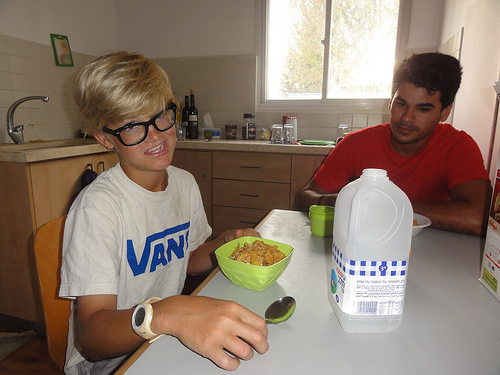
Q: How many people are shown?
A: 2.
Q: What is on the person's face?
A: Glasses.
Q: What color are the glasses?
A: Black.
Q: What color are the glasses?
A: Black.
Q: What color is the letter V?
A: Blue.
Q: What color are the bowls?
A: Green.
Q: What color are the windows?
A: White.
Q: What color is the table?
A: White.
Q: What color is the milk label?
A: White.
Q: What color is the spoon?
A: Silver.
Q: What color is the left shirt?
A: White.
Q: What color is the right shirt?
A: Red.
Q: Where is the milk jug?
A: Tabletop.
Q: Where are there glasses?
A: Boy's face.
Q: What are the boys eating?
A: Cereal.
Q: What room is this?
A: Kitchen.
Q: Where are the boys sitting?
A: Kitchen table.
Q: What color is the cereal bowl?
A: Green.